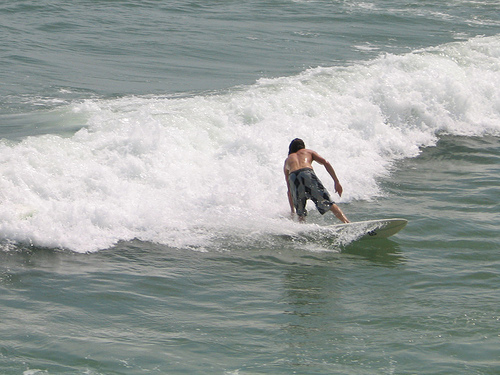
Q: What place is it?
A: It is an ocean.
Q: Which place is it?
A: It is an ocean.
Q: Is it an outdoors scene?
A: Yes, it is outdoors.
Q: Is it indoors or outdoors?
A: It is outdoors.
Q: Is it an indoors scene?
A: No, it is outdoors.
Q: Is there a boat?
A: No, there are no boats.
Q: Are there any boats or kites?
A: No, there are no boats or kites.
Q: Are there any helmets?
A: No, there are no helmets.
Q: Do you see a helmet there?
A: No, there are no helmets.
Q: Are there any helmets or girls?
A: No, there are no helmets or girls.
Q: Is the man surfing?
A: Yes, the man is surfing.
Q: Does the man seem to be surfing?
A: Yes, the man is surfing.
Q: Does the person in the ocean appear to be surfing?
A: Yes, the man is surfing.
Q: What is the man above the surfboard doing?
A: The man is surfing.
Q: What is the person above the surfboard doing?
A: The man is surfing.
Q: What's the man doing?
A: The man is surfing.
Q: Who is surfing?
A: The man is surfing.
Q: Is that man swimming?
A: No, the man is surfing.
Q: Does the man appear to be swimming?
A: No, the man is surfing.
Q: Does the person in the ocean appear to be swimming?
A: No, the man is surfing.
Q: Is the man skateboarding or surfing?
A: The man is surfing.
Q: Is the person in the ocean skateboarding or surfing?
A: The man is surfing.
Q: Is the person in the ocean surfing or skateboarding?
A: The man is surfing.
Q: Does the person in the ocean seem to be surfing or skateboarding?
A: The man is surfing.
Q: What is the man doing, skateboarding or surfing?
A: The man is surfing.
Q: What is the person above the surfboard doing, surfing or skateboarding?
A: The man is surfing.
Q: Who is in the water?
A: The man is in the water.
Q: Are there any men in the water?
A: Yes, there is a man in the water.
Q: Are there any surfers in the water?
A: No, there is a man in the water.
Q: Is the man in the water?
A: Yes, the man is in the water.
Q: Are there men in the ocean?
A: Yes, there is a man in the ocean.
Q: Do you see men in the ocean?
A: Yes, there is a man in the ocean.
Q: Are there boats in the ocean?
A: No, there is a man in the ocean.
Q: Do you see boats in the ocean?
A: No, there is a man in the ocean.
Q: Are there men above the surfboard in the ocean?
A: Yes, there is a man above the surf board.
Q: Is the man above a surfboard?
A: Yes, the man is above a surfboard.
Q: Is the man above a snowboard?
A: No, the man is above a surfboard.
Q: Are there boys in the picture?
A: No, there are no boys.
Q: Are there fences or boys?
A: No, there are no boys or fences.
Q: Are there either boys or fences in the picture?
A: No, there are no boys or fences.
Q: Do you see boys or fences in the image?
A: No, there are no boys or fences.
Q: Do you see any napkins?
A: No, there are no napkins.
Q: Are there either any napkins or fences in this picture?
A: No, there are no napkins or fences.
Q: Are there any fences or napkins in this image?
A: No, there are no napkins or fences.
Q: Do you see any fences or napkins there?
A: No, there are no napkins or fences.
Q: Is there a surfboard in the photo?
A: Yes, there is a surfboard.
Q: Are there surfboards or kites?
A: Yes, there is a surfboard.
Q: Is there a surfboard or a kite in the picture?
A: Yes, there is a surfboard.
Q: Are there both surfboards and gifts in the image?
A: No, there is a surfboard but no gifts.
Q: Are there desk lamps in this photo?
A: No, there are no desk lamps.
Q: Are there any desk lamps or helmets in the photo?
A: No, there are no desk lamps or helmets.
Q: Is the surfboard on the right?
A: Yes, the surfboard is on the right of the image.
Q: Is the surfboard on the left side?
A: No, the surfboard is on the right of the image.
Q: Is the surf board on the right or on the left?
A: The surf board is on the right of the image.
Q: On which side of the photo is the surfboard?
A: The surfboard is on the right of the image.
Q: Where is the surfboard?
A: The surfboard is in the ocean.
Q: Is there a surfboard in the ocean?
A: Yes, there is a surfboard in the ocean.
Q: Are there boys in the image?
A: No, there are no boys.